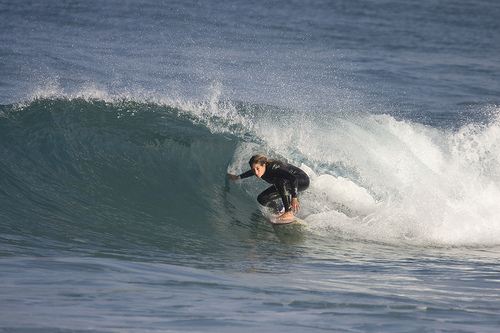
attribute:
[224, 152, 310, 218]
surfer — woman, surfing, squatting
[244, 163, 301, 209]
wetsuit — black, neoprene, shiny, wet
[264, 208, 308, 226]
surfboard — white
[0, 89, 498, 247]
wave — breaking, white, turbulent, crashing, forming, splashing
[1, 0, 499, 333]
ocean — blue, white, wavy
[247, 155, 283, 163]
hair — long, ponytail, wet, blond, brown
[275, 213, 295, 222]
foot — bare